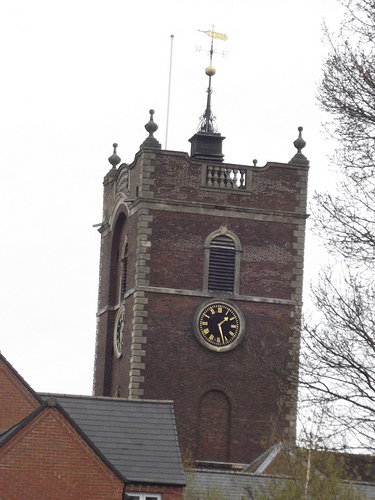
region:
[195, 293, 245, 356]
black clock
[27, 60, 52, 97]
white clouds in blue sky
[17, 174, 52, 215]
white clouds in blue sky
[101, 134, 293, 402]
brown clock tower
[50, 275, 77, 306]
white clouds in blue sky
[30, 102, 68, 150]
white clouds in blue sky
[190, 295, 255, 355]
clock on the side of the tower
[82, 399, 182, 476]
brown roof on the business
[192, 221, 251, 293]
arched louvered window in the tower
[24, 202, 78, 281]
white sky next to the tower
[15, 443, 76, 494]
red brick wall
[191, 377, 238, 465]
brick arch on the side of the tower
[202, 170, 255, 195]
window with spindles in the open area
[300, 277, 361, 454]
tree in front of the window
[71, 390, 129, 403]
top of the roof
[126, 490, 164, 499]
top of the window on the building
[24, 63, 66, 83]
white clouds in blue sky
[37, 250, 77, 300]
white clouds in blue sky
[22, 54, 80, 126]
white clouds in blue sky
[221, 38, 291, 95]
white clouds in blue sky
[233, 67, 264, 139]
white clouds in blue sky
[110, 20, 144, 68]
white clouds in blue sky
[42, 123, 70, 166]
white clouds in blue sky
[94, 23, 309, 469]
a clock tower with two clocks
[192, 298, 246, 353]
a clock tower showing 1:26 as the time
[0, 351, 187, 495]
a red brick building with a gray roof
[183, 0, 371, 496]
trees growing in front of the building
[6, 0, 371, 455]
a white colored sky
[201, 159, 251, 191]
a gray balcony railing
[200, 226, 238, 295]
an arched window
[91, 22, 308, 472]
a weather vane on top of the clock tower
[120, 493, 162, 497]
a window on the house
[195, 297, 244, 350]
a clock with Roman Numberals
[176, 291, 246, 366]
clock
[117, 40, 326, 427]
brown tower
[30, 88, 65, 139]
white clouds in blue sky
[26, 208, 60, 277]
white clouds in blue sky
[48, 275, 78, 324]
white clouds in blue sky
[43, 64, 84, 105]
white clouds in blue sky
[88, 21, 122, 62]
white clouds in blue sky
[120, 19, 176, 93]
white clouds in blue sky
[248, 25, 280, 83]
white clouds in blue sky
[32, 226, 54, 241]
white clouds in blue sky